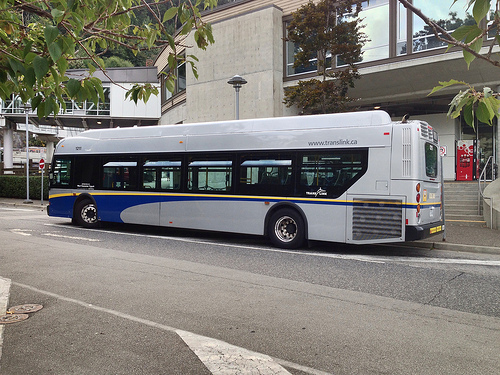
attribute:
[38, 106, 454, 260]
bus — large, white, translink, blue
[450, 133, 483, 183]
vending machine — red, white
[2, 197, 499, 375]
city street — asphalt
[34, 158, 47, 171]
stop sign — red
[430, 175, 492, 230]
stairs — cement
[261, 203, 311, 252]
tire — round, rear wheel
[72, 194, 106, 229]
tire — black, round, front wheel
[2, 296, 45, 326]
man hole cover — metal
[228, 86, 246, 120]
metal pole — white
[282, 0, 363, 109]
tree — tall